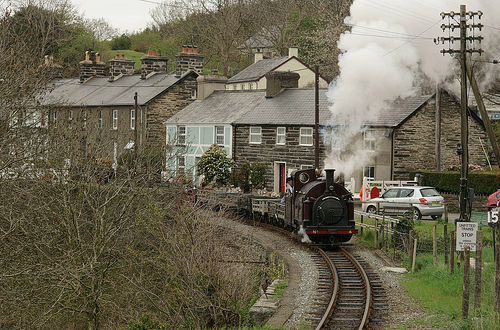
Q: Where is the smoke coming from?
A: The train.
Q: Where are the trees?
A: Next to the track.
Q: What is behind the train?
A: Buildings.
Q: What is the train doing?
A: Moving.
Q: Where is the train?
A: On the tracks.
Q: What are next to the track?
A: Houses.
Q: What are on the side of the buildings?
A: Many windows.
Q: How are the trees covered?
A: Bare.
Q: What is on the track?
A: A small train.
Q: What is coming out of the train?
A: A cloud of steam.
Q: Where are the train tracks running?
A: Alongside a building.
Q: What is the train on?
A: Train tracks.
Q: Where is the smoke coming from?
A: The trains engine.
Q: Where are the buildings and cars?
A: Behind the train.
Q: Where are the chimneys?
A: On the roofs.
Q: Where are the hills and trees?
A: Behind the buildings.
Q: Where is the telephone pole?
A: Far right.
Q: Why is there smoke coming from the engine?
A: The engine is steam powered.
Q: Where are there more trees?
A: To the front and right of the train.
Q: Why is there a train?
A: Travelling.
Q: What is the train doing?
A: Moving.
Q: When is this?
A: Daytime.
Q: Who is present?
A: No one.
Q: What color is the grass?
A: Green.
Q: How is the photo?
A: Clear.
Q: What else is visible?
A: Cars.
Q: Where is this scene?
A: Train tracks.